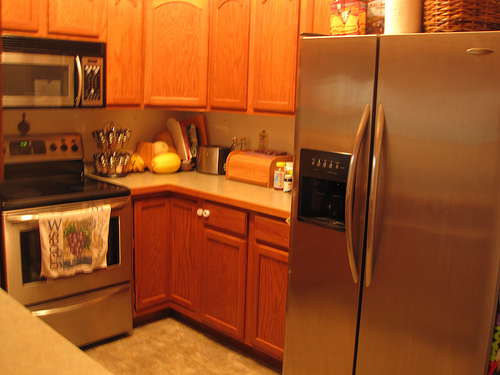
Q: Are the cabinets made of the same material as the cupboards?
A: Yes, both the cabinets and the cupboards are made of wood.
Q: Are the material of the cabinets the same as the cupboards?
A: Yes, both the cabinets and the cupboards are made of wood.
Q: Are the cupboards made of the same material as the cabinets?
A: Yes, both the cupboards and the cabinets are made of wood.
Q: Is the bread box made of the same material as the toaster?
A: No, the bread box is made of wood and the toaster is made of metal.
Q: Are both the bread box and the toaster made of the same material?
A: No, the bread box is made of wood and the toaster is made of metal.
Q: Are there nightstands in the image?
A: No, there are no nightstands.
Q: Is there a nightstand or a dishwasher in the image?
A: No, there are no nightstands or dishwashers.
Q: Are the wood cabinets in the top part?
A: Yes, the cabinets are in the top of the image.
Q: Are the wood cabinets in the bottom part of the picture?
A: No, the cabinets are in the top of the image.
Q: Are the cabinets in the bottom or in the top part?
A: The cabinets are in the top of the image.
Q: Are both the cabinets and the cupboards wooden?
A: Yes, both the cabinets and the cupboards are wooden.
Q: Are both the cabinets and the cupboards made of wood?
A: Yes, both the cabinets and the cupboards are made of wood.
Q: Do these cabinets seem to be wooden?
A: Yes, the cabinets are wooden.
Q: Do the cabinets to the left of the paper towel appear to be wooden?
A: Yes, the cabinets are wooden.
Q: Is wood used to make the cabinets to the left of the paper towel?
A: Yes, the cabinets are made of wood.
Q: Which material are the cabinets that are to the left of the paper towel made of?
A: The cabinets are made of wood.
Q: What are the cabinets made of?
A: The cabinets are made of wood.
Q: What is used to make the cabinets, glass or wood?
A: The cabinets are made of wood.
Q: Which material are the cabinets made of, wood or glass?
A: The cabinets are made of wood.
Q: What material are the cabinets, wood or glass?
A: The cabinets are made of wood.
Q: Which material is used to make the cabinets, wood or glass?
A: The cabinets are made of wood.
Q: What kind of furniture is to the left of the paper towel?
A: The pieces of furniture are cabinets.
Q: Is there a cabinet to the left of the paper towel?
A: Yes, there are cabinets to the left of the paper towel.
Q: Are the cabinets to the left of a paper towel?
A: Yes, the cabinets are to the left of a paper towel.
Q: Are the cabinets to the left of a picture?
A: No, the cabinets are to the left of a paper towel.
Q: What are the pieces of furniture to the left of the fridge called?
A: The pieces of furniture are cabinets.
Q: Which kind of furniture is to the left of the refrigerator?
A: The pieces of furniture are cabinets.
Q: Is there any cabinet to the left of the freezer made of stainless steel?
A: Yes, there are cabinets to the left of the fridge.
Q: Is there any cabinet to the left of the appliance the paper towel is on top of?
A: Yes, there are cabinets to the left of the fridge.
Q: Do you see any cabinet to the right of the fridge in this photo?
A: No, the cabinets are to the left of the fridge.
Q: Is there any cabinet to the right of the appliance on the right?
A: No, the cabinets are to the left of the fridge.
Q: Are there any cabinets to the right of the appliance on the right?
A: No, the cabinets are to the left of the fridge.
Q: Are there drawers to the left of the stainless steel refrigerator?
A: No, there are cabinets to the left of the refrigerator.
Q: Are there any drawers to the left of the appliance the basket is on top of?
A: No, there are cabinets to the left of the refrigerator.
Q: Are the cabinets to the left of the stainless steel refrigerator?
A: Yes, the cabinets are to the left of the refrigerator.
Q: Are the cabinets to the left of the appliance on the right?
A: Yes, the cabinets are to the left of the refrigerator.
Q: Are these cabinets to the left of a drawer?
A: No, the cabinets are to the left of the refrigerator.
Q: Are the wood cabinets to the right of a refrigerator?
A: No, the cabinets are to the left of a refrigerator.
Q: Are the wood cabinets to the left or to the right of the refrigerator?
A: The cabinets are to the left of the refrigerator.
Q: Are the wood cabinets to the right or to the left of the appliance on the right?
A: The cabinets are to the left of the refrigerator.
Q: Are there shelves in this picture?
A: No, there are no shelves.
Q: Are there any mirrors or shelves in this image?
A: No, there are no shelves or mirrors.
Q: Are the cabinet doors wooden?
A: Yes, the cabinet doors are wooden.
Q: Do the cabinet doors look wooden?
A: Yes, the cabinet doors are wooden.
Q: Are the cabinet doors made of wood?
A: Yes, the cabinet doors are made of wood.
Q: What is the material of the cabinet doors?
A: The cabinet doors are made of wood.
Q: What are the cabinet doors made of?
A: The cabinet doors are made of wood.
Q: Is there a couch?
A: No, there are no couches.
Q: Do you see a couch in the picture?
A: No, there are no couches.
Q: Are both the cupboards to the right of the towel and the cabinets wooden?
A: Yes, both the cupboards and the cabinets are wooden.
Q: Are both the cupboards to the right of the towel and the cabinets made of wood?
A: Yes, both the cupboards and the cabinets are made of wood.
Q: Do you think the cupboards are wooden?
A: Yes, the cupboards are wooden.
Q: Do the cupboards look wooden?
A: Yes, the cupboards are wooden.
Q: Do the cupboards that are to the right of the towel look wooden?
A: Yes, the cupboards are wooden.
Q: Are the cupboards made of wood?
A: Yes, the cupboards are made of wood.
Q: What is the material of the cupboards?
A: The cupboards are made of wood.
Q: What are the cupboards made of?
A: The cupboards are made of wood.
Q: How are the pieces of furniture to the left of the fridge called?
A: The pieces of furniture are cupboards.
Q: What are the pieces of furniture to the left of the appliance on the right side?
A: The pieces of furniture are cupboards.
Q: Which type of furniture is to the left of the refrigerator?
A: The pieces of furniture are cupboards.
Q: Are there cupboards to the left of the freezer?
A: Yes, there are cupboards to the left of the freezer.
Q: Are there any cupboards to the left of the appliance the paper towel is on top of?
A: Yes, there are cupboards to the left of the freezer.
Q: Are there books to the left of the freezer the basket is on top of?
A: No, there are cupboards to the left of the refrigerator.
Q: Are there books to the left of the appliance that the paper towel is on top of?
A: No, there are cupboards to the left of the refrigerator.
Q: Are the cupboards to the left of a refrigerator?
A: Yes, the cupboards are to the left of a refrigerator.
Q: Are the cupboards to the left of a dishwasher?
A: No, the cupboards are to the left of a refrigerator.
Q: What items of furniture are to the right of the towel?
A: The pieces of furniture are cupboards.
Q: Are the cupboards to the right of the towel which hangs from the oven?
A: Yes, the cupboards are to the right of the towel.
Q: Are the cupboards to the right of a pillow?
A: No, the cupboards are to the right of the towel.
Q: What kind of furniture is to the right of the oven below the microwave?
A: The pieces of furniture are cupboards.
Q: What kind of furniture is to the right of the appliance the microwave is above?
A: The pieces of furniture are cupboards.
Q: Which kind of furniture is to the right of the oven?
A: The pieces of furniture are cupboards.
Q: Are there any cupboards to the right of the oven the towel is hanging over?
A: Yes, there are cupboards to the right of the oven.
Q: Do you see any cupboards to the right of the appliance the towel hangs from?
A: Yes, there are cupboards to the right of the oven.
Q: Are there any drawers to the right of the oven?
A: No, there are cupboards to the right of the oven.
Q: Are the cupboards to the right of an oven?
A: Yes, the cupboards are to the right of an oven.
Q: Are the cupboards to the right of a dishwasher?
A: No, the cupboards are to the right of an oven.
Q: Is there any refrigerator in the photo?
A: Yes, there is a refrigerator.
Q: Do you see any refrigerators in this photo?
A: Yes, there is a refrigerator.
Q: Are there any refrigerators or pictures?
A: Yes, there is a refrigerator.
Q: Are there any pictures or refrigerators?
A: Yes, there is a refrigerator.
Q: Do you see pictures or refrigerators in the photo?
A: Yes, there is a refrigerator.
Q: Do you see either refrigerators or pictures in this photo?
A: Yes, there is a refrigerator.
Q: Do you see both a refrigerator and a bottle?
A: Yes, there are both a refrigerator and a bottle.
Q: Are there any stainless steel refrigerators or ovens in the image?
A: Yes, there is a stainless steel refrigerator.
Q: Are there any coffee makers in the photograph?
A: No, there are no coffee makers.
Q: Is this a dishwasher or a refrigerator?
A: This is a refrigerator.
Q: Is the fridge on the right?
A: Yes, the fridge is on the right of the image.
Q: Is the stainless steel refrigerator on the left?
A: No, the refrigerator is on the right of the image.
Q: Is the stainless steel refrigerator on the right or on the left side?
A: The fridge is on the right of the image.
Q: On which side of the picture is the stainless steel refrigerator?
A: The freezer is on the right of the image.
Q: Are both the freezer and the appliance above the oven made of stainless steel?
A: Yes, both the freezer and the microwave are made of stainless steel.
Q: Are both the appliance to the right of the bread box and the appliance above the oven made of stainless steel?
A: Yes, both the freezer and the microwave are made of stainless steel.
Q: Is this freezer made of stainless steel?
A: Yes, the freezer is made of stainless steel.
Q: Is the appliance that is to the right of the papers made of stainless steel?
A: Yes, the freezer is made of stainless steel.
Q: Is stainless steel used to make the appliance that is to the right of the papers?
A: Yes, the freezer is made of stainless steel.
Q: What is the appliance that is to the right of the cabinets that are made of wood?
A: The appliance is a refrigerator.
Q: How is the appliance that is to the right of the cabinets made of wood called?
A: The appliance is a refrigerator.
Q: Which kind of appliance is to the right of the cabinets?
A: The appliance is a refrigerator.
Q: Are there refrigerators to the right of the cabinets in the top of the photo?
A: Yes, there is a refrigerator to the right of the cabinets.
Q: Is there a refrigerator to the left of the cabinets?
A: No, the refrigerator is to the right of the cabinets.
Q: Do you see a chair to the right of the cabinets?
A: No, there is a refrigerator to the right of the cabinets.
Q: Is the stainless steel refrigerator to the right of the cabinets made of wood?
A: Yes, the refrigerator is to the right of the cabinets.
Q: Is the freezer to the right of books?
A: No, the freezer is to the right of the cabinets.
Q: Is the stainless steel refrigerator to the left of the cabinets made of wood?
A: No, the refrigerator is to the right of the cabinets.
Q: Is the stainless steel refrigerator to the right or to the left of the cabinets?
A: The refrigerator is to the right of the cabinets.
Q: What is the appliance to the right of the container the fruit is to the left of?
A: The appliance is a refrigerator.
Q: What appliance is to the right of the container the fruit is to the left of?
A: The appliance is a refrigerator.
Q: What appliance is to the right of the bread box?
A: The appliance is a refrigerator.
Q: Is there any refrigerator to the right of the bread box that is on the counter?
A: Yes, there is a refrigerator to the right of the bread box.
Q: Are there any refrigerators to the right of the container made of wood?
A: Yes, there is a refrigerator to the right of the bread box.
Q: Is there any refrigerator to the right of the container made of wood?
A: Yes, there is a refrigerator to the right of the bread box.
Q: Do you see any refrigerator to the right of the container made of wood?
A: Yes, there is a refrigerator to the right of the bread box.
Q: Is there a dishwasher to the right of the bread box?
A: No, there is a refrigerator to the right of the bread box.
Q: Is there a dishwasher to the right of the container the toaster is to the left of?
A: No, there is a refrigerator to the right of the bread box.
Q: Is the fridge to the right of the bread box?
A: Yes, the fridge is to the right of the bread box.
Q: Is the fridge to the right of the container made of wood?
A: Yes, the fridge is to the right of the bread box.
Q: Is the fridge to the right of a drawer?
A: No, the fridge is to the right of the bread box.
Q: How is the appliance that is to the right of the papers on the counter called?
A: The appliance is a refrigerator.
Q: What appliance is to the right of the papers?
A: The appliance is a refrigerator.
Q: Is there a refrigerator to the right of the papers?
A: Yes, there is a refrigerator to the right of the papers.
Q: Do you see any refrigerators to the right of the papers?
A: Yes, there is a refrigerator to the right of the papers.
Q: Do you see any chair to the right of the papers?
A: No, there is a refrigerator to the right of the papers.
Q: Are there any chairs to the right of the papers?
A: No, there is a refrigerator to the right of the papers.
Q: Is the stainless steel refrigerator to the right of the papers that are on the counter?
A: Yes, the refrigerator is to the right of the papers.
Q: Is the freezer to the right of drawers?
A: No, the freezer is to the right of the papers.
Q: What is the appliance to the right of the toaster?
A: The appliance is a refrigerator.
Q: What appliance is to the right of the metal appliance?
A: The appliance is a refrigerator.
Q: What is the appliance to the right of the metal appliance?
A: The appliance is a refrigerator.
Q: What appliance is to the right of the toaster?
A: The appliance is a refrigerator.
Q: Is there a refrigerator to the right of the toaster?
A: Yes, there is a refrigerator to the right of the toaster.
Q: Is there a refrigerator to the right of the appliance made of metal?
A: Yes, there is a refrigerator to the right of the toaster.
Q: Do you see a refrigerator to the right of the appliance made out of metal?
A: Yes, there is a refrigerator to the right of the toaster.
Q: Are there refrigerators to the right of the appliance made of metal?
A: Yes, there is a refrigerator to the right of the toaster.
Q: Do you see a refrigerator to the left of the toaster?
A: No, the refrigerator is to the right of the toaster.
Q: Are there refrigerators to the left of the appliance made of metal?
A: No, the refrigerator is to the right of the toaster.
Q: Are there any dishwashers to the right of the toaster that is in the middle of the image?
A: No, there is a refrigerator to the right of the toaster.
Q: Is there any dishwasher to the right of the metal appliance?
A: No, there is a refrigerator to the right of the toaster.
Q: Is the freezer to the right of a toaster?
A: Yes, the freezer is to the right of a toaster.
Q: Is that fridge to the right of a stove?
A: No, the fridge is to the right of a toaster.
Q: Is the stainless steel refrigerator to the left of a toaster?
A: No, the refrigerator is to the right of a toaster.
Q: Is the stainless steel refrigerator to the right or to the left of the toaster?
A: The refrigerator is to the right of the toaster.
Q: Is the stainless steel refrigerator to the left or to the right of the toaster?
A: The refrigerator is to the right of the toaster.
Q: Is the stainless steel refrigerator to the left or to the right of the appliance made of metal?
A: The refrigerator is to the right of the toaster.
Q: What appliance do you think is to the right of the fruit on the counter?
A: The appliance is a refrigerator.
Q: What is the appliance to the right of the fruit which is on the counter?
A: The appliance is a refrigerator.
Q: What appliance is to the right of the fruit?
A: The appliance is a refrigerator.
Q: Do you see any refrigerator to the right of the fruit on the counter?
A: Yes, there is a refrigerator to the right of the fruit.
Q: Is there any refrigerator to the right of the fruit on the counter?
A: Yes, there is a refrigerator to the right of the fruit.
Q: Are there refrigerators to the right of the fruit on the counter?
A: Yes, there is a refrigerator to the right of the fruit.